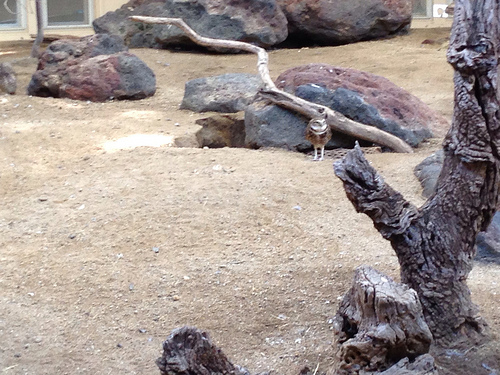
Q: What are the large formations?
A: Rocks.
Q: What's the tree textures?
A: Rough.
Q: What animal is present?
A: Owl.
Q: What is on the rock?
A: A dead tree limb.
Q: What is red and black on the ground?
A: A rock.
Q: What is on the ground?
A: Dirt and rocks.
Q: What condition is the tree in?
A: Dead with no leaves.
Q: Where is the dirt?
A: On the ground.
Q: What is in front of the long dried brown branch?
A: A bird.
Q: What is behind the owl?
A: A large rock.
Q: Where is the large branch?
A: On the rock.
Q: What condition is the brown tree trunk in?
A: Dead.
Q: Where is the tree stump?
A: In the dirt.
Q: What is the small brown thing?
A: Owl.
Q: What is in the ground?
A: Dirt.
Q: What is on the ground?
A: Dirt.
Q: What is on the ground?
A: A dirt.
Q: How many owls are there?
A: One.